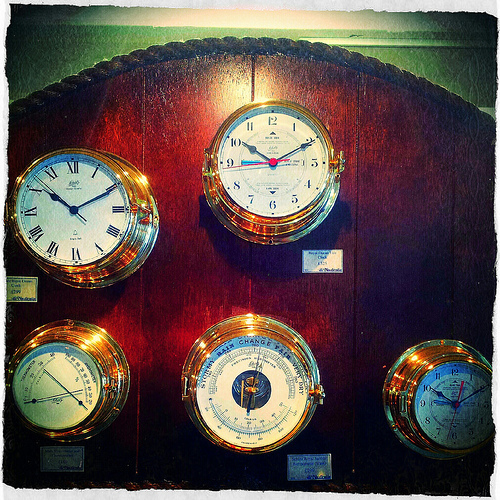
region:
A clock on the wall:
[206, 101, 338, 247]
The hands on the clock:
[240, 136, 310, 162]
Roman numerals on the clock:
[11, 146, 148, 286]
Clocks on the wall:
[10, 101, 490, 451]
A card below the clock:
[300, 250, 340, 270]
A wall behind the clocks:
[6, 40, 496, 495]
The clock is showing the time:
[197, 100, 337, 242]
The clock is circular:
[200, 100, 340, 242]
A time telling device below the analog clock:
[180, 313, 322, 453]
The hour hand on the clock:
[238, 143, 276, 165]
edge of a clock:
[296, 370, 324, 443]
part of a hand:
[222, 355, 255, 404]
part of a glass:
[271, 403, 283, 424]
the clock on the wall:
[201, 100, 346, 247]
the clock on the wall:
[384, 337, 493, 457]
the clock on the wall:
[10, 149, 157, 289]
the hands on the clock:
[219, 134, 315, 174]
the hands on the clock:
[428, 379, 480, 442]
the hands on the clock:
[31, 172, 108, 225]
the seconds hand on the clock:
[221, 158, 290, 171]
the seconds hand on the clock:
[443, 380, 464, 439]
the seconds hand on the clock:
[32, 172, 89, 223]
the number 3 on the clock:
[310, 155, 319, 168]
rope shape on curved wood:
[13, 33, 494, 117]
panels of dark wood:
[11, 58, 486, 483]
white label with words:
[300, 248, 342, 273]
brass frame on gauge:
[181, 314, 322, 456]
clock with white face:
[218, 104, 332, 217]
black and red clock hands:
[226, 138, 311, 173]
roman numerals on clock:
[21, 159, 126, 261]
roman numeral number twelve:
[66, 160, 80, 176]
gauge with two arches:
[21, 353, 94, 411]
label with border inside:
[37, 442, 87, 472]